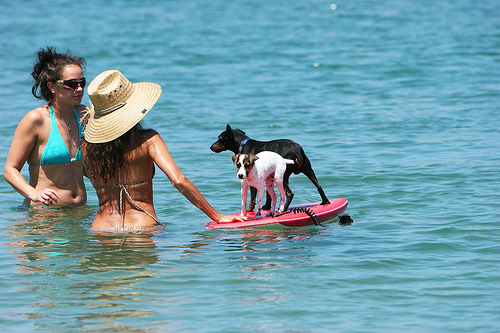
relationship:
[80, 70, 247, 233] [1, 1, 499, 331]
person in middle of water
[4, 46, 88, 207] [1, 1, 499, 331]
person in middle of water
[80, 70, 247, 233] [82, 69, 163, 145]
person wearing hat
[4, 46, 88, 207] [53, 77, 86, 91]
person wearing sunglasses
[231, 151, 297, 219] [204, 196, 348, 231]
dog on top of surfboard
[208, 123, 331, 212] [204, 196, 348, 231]
dog on top of surfboard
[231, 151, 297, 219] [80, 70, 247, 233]
dog swimming with person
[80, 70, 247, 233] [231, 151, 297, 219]
person with dog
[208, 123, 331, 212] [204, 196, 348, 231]
dog standing on surfboard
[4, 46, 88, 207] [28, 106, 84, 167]
person wearing bikini top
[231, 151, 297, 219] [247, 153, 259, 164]
dog has ear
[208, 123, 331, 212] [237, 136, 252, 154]
dog wearing collar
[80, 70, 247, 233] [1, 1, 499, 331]
person standing in water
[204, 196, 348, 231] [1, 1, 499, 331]
surfboard floating in water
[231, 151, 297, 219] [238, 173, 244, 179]
dog has nose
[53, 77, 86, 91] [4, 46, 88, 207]
sunglasses on front of person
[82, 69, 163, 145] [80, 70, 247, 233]
hat on top of person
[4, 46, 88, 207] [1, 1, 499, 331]
person standing in water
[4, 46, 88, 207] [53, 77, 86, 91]
person has sunglasses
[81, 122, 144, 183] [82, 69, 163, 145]
hair under hat